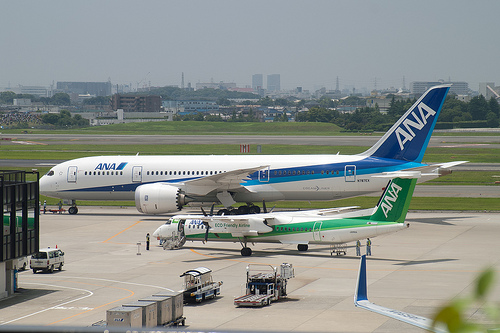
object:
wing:
[351, 252, 500, 333]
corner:
[372, 272, 500, 333]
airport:
[0, 79, 500, 333]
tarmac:
[0, 193, 500, 333]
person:
[353, 238, 363, 257]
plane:
[148, 167, 443, 258]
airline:
[148, 170, 423, 258]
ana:
[379, 181, 404, 220]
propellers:
[196, 201, 216, 245]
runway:
[0, 129, 500, 148]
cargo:
[88, 290, 191, 328]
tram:
[173, 264, 226, 306]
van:
[27, 245, 69, 276]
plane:
[21, 78, 474, 220]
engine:
[132, 180, 196, 215]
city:
[0, 64, 499, 139]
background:
[0, 0, 500, 143]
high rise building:
[250, 72, 264, 89]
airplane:
[350, 253, 499, 332]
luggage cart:
[227, 255, 300, 311]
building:
[1, 167, 45, 303]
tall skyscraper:
[265, 72, 283, 93]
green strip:
[153, 179, 412, 241]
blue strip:
[61, 85, 453, 195]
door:
[175, 217, 189, 237]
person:
[42, 199, 49, 214]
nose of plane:
[22, 162, 65, 203]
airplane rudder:
[352, 81, 454, 163]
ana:
[392, 100, 438, 151]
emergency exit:
[312, 219, 324, 244]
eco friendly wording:
[213, 221, 252, 229]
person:
[55, 199, 65, 215]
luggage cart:
[37, 206, 72, 216]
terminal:
[0, 120, 74, 332]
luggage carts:
[100, 304, 144, 333]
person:
[145, 231, 152, 251]